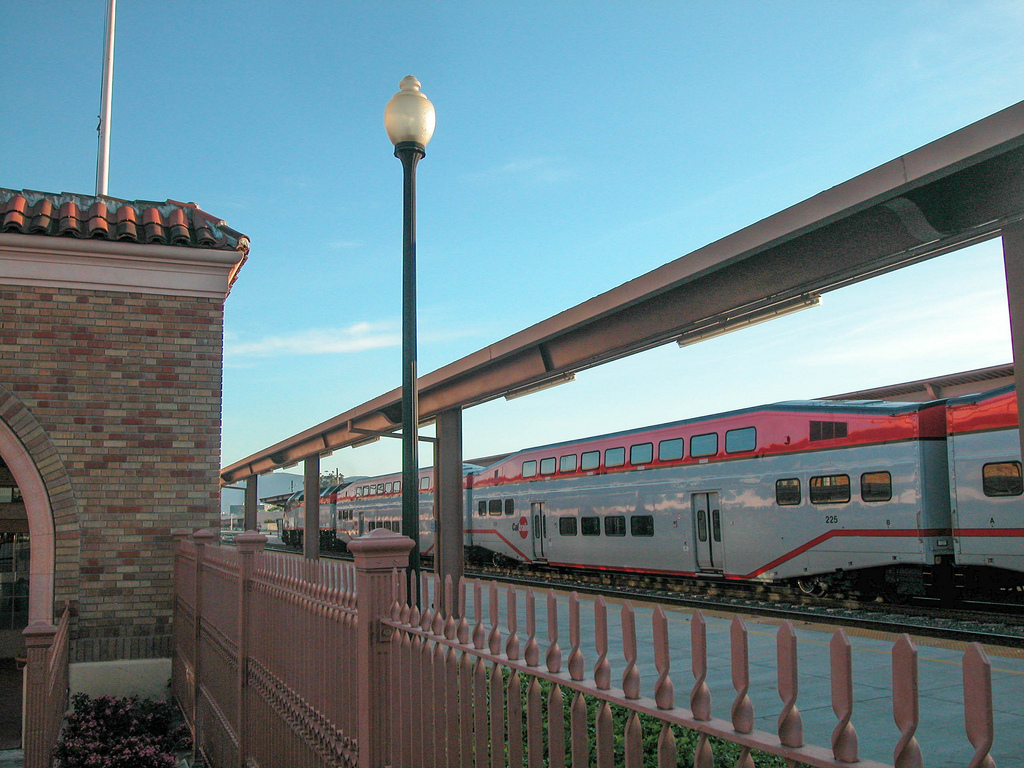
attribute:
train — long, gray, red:
[284, 400, 1022, 606]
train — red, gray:
[279, 389, 1022, 580]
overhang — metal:
[225, 102, 1019, 479]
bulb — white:
[383, 70, 437, 165]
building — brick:
[0, 190, 244, 744]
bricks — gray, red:
[4, 286, 224, 654]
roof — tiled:
[6, 168, 245, 255]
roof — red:
[4, 163, 273, 345]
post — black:
[314, 33, 488, 492]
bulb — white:
[288, 23, 448, 161]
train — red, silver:
[459, 367, 834, 563]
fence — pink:
[324, 561, 591, 699]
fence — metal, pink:
[165, 532, 1014, 761]